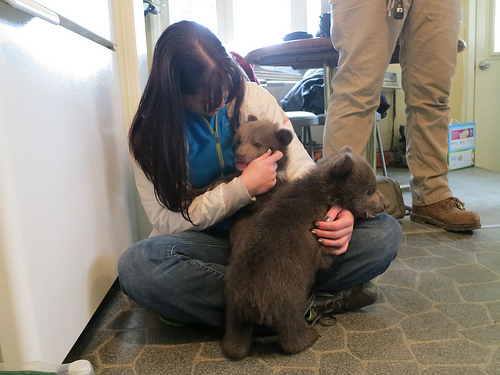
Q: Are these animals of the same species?
A: Yes, all the animals are bears.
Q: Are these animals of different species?
A: No, all the animals are bears.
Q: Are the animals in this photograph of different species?
A: No, all the animals are bears.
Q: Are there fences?
A: No, there are no fences.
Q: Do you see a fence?
A: No, there are no fences.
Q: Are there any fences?
A: No, there are no fences.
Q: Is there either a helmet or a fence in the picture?
A: No, there are no fences or helmets.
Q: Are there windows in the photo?
A: Yes, there is a window.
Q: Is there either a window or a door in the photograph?
A: Yes, there is a window.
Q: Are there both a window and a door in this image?
A: Yes, there are both a window and a door.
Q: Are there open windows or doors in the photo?
A: Yes, there is an open window.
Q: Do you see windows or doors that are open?
A: Yes, the window is open.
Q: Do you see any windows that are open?
A: Yes, there is an open window.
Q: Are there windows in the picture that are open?
A: Yes, there is a window that is open.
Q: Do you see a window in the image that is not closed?
A: Yes, there is a open window.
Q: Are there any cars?
A: No, there are no cars.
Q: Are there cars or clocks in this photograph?
A: No, there are no cars or clocks.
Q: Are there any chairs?
A: Yes, there is a chair.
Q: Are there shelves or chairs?
A: Yes, there is a chair.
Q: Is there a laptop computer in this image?
A: No, there are no laptops.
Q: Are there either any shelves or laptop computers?
A: No, there are no laptop computers or shelves.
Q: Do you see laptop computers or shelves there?
A: No, there are no laptop computers or shelves.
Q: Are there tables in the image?
A: Yes, there is a table.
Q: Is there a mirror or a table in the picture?
A: Yes, there is a table.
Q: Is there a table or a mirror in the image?
A: Yes, there is a table.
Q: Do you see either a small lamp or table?
A: Yes, there is a small table.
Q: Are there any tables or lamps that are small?
A: Yes, the table is small.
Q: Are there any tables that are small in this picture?
A: Yes, there is a small table.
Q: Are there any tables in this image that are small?
A: Yes, there is a table that is small.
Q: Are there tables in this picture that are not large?
A: Yes, there is a small table.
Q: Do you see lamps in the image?
A: No, there are no lamps.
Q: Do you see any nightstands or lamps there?
A: No, there are no lamps or nightstands.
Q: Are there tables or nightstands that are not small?
A: No, there is a table but it is small.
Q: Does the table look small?
A: Yes, the table is small.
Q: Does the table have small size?
A: Yes, the table is small.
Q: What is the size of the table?
A: The table is small.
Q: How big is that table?
A: The table is small.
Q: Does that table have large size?
A: No, the table is small.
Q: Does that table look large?
A: No, the table is small.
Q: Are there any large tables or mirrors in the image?
A: No, there is a table but it is small.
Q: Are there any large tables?
A: No, there is a table but it is small.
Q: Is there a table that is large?
A: No, there is a table but it is small.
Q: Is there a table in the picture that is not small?
A: No, there is a table but it is small.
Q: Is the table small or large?
A: The table is small.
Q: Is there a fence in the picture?
A: No, there are no fences.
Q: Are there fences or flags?
A: No, there are no fences or flags.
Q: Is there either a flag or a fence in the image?
A: No, there are no fences or flags.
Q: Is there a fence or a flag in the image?
A: No, there are no fences or flags.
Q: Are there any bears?
A: Yes, there is a bear.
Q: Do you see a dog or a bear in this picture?
A: Yes, there is a bear.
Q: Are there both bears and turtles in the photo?
A: No, there is a bear but no turtles.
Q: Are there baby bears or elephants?
A: Yes, there is a baby bear.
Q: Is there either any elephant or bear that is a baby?
A: Yes, the bear is a baby.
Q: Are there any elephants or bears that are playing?
A: Yes, the bear is playing.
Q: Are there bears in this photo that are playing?
A: Yes, there is a bear that is playing.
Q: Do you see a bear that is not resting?
A: Yes, there is a bear that is playing .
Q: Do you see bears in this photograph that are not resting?
A: Yes, there is a bear that is playing .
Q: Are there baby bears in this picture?
A: Yes, there is a baby bear.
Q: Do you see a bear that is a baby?
A: Yes, there is a bear that is a baby.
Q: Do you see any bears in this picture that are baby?
A: Yes, there is a bear that is a baby.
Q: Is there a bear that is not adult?
A: Yes, there is an baby bear.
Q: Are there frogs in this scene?
A: No, there are no frogs.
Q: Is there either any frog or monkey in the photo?
A: No, there are no frogs or monkeys.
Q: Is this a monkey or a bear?
A: This is a bear.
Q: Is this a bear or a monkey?
A: This is a bear.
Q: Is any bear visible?
A: Yes, there is a bear.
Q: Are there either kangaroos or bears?
A: Yes, there is a bear.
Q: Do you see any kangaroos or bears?
A: Yes, there is a bear.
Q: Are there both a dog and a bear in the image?
A: No, there is a bear but no dogs.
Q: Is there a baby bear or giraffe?
A: Yes, there is a baby bear.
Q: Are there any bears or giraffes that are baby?
A: Yes, the bear is a baby.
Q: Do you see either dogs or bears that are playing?
A: Yes, the bear is playing.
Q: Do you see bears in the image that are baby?
A: Yes, there is a baby bear.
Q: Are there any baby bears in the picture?
A: Yes, there is a baby bear.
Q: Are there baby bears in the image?
A: Yes, there is a baby bear.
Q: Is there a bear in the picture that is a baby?
A: Yes, there is a bear that is a baby.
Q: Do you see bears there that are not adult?
A: Yes, there is an baby bear.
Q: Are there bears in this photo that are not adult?
A: Yes, there is an baby bear.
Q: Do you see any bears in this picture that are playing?
A: Yes, there is a bear that is playing.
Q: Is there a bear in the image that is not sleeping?
A: Yes, there is a bear that is playing.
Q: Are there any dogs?
A: No, there are no dogs.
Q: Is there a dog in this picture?
A: No, there are no dogs.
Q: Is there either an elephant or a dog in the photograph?
A: No, there are no dogs or elephants.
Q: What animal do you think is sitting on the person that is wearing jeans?
A: The bear is sitting on the girl.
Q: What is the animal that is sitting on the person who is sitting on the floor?
A: The animal is a bear.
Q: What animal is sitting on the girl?
A: The animal is a bear.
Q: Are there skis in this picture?
A: No, there are no skis.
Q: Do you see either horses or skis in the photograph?
A: No, there are no skis or horses.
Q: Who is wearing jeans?
A: The girl is wearing jeans.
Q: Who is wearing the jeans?
A: The girl is wearing jeans.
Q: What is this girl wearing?
A: The girl is wearing jeans.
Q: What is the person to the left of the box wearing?
A: The girl is wearing jeans.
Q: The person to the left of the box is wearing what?
A: The girl is wearing jeans.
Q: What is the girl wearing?
A: The girl is wearing jeans.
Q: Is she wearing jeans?
A: Yes, the girl is wearing jeans.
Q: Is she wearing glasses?
A: No, the girl is wearing jeans.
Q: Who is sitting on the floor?
A: The girl is sitting on the floor.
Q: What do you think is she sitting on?
A: The girl is sitting on the floor.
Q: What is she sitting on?
A: The girl is sitting on the floor.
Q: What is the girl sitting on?
A: The girl is sitting on the floor.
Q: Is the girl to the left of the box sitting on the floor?
A: Yes, the girl is sitting on the floor.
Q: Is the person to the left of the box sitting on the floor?
A: Yes, the girl is sitting on the floor.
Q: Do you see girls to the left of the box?
A: Yes, there is a girl to the left of the box.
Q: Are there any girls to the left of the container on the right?
A: Yes, there is a girl to the left of the box.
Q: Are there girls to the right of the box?
A: No, the girl is to the left of the box.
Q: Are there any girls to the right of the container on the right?
A: No, the girl is to the left of the box.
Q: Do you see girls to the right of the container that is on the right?
A: No, the girl is to the left of the box.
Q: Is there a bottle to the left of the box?
A: No, there is a girl to the left of the box.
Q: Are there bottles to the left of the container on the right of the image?
A: No, there is a girl to the left of the box.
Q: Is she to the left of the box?
A: Yes, the girl is to the left of the box.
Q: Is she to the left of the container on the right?
A: Yes, the girl is to the left of the box.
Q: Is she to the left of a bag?
A: No, the girl is to the left of the box.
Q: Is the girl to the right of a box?
A: No, the girl is to the left of a box.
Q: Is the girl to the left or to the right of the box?
A: The girl is to the left of the box.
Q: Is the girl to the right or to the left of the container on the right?
A: The girl is to the left of the box.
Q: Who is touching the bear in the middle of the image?
A: The girl is touching the bear.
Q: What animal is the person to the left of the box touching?
A: The girl is touching the bear.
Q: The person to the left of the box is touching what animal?
A: The girl is touching the bear.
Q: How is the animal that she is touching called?
A: The animal is a bear.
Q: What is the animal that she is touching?
A: The animal is a bear.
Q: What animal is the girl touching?
A: The girl is touching the bear.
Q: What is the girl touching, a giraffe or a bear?
A: The girl is touching a bear.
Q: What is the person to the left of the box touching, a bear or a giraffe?
A: The girl is touching a bear.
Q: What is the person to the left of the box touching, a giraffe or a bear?
A: The girl is touching a bear.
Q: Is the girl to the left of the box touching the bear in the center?
A: Yes, the girl is touching the bear.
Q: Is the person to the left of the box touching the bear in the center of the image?
A: Yes, the girl is touching the bear.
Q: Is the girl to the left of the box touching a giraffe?
A: No, the girl is touching the bear.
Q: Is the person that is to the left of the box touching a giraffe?
A: No, the girl is touching the bear.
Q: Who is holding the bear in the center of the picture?
A: The girl is holding the bear.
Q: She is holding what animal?
A: The girl is holding the bear.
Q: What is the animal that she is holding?
A: The animal is a bear.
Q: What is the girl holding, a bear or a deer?
A: The girl is holding a bear.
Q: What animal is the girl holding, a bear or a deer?
A: The girl is holding a bear.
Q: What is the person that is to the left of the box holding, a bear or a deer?
A: The girl is holding a bear.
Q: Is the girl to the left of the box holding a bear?
A: Yes, the girl is holding a bear.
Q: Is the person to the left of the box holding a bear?
A: Yes, the girl is holding a bear.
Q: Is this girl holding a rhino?
A: No, the girl is holding a bear.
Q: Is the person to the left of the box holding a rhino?
A: No, the girl is holding a bear.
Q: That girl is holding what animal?
A: The girl is holding the bear.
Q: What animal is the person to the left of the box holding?
A: The girl is holding the bear.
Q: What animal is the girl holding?
A: The girl is holding the bear.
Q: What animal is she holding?
A: The girl is holding the bear.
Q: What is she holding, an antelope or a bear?
A: The girl is holding a bear.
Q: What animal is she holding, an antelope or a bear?
A: The girl is holding a bear.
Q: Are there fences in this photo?
A: No, there are no fences.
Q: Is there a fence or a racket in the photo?
A: No, there are no fences or rackets.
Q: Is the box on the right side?
A: Yes, the box is on the right of the image.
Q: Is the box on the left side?
A: No, the box is on the right of the image.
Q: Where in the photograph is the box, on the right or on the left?
A: The box is on the right of the image.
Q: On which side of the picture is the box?
A: The box is on the right of the image.